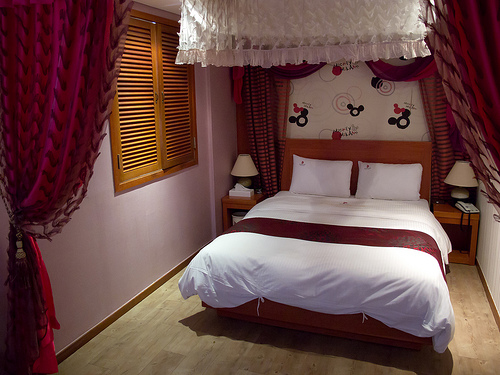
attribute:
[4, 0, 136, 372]
curtain — red textured , burgandy 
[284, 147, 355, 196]
pillow — bright white 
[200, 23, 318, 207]
curtain — red textured 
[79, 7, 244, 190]
window — light brown slatted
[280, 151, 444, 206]
white pillows — two white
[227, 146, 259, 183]
lampshade — white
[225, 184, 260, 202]
tissues — box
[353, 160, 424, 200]
pillow — bright white 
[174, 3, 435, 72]
canopy — white 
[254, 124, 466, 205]
headboard — brown wooden 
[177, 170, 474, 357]
comforter — bright white, bright, white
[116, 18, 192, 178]
blinds — wooden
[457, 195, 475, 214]
phone — white landline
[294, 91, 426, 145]
design — corner